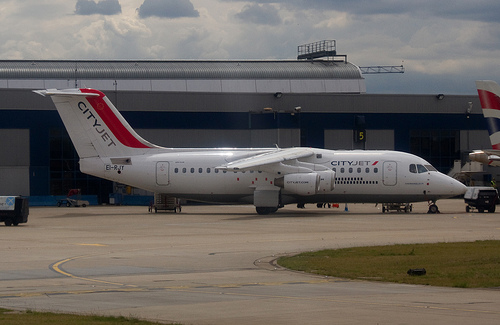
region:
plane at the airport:
[66, 110, 460, 269]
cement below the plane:
[147, 221, 226, 283]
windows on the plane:
[166, 140, 233, 193]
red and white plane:
[50, 87, 422, 264]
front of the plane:
[389, 133, 450, 193]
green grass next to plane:
[446, 244, 490, 278]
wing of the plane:
[218, 121, 317, 201]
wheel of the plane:
[423, 189, 450, 220]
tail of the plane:
[436, 75, 497, 127]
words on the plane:
[62, 99, 132, 165]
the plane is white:
[114, 22, 346, 296]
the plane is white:
[46, 53, 443, 323]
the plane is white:
[44, 50, 361, 208]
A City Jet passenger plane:
[36, 67, 490, 241]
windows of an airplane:
[166, 161, 217, 176]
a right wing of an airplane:
[207, 146, 307, 177]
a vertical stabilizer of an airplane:
[70, 70, 158, 147]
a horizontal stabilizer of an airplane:
[38, 77, 108, 118]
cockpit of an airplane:
[401, 152, 462, 200]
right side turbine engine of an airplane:
[273, 167, 353, 200]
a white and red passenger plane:
[12, 35, 477, 245]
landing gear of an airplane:
[410, 197, 448, 224]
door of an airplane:
[371, 156, 401, 200]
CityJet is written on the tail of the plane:
[72, 103, 119, 155]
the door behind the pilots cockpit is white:
[383, 161, 395, 186]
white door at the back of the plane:
[155, 161, 171, 186]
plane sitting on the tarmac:
[23, 86, 471, 221]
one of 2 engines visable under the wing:
[254, 164, 322, 198]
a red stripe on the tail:
[78, 91, 160, 156]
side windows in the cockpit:
[411, 161, 427, 175]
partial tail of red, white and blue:
[476, 79, 499, 154]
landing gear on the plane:
[428, 201, 441, 220]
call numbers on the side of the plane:
[100, 163, 134, 175]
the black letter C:
[330, 156, 340, 171]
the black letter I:
[333, 156, 342, 167]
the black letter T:
[339, 157, 348, 168]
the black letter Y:
[344, 157, 356, 167]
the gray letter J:
[351, 156, 360, 168]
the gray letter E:
[358, 160, 367, 170]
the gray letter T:
[366, 157, 373, 168]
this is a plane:
[30, 61, 470, 241]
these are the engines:
[265, 157, 345, 214]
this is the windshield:
[402, 155, 443, 174]